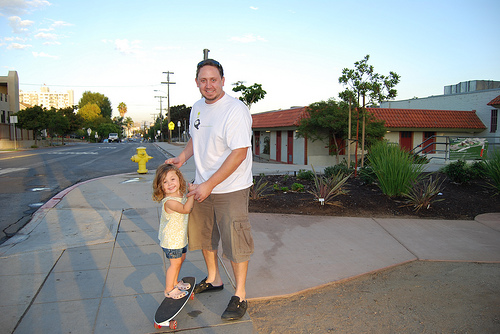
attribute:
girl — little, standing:
[159, 161, 195, 296]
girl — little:
[153, 167, 203, 298]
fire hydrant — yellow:
[127, 144, 157, 175]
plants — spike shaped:
[363, 140, 421, 201]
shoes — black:
[188, 276, 248, 326]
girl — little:
[143, 163, 203, 302]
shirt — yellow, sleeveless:
[153, 192, 193, 247]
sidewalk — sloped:
[1, 148, 185, 332]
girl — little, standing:
[145, 164, 207, 300]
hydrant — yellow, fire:
[127, 142, 154, 182]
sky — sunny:
[4, 4, 498, 118]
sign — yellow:
[160, 116, 180, 134]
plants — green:
[358, 135, 436, 211]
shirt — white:
[181, 94, 263, 199]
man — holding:
[163, 56, 260, 320]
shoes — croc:
[163, 277, 199, 301]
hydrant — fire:
[125, 140, 157, 178]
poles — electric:
[146, 67, 177, 142]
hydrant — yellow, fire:
[128, 141, 162, 185]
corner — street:
[82, 159, 193, 208]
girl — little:
[149, 160, 206, 306]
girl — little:
[148, 155, 203, 301]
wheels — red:
[148, 291, 204, 331]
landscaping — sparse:
[256, 145, 498, 219]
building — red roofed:
[245, 98, 495, 180]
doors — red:
[398, 129, 444, 158]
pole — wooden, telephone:
[157, 65, 188, 148]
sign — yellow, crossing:
[165, 118, 179, 133]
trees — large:
[20, 85, 131, 148]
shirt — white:
[187, 93, 252, 200]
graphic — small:
[184, 115, 210, 140]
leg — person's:
[165, 257, 181, 297]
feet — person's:
[163, 288, 192, 302]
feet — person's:
[159, 284, 195, 300]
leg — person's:
[205, 248, 221, 282]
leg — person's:
[232, 257, 246, 302]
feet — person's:
[194, 279, 224, 291]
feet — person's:
[219, 297, 248, 322]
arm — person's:
[190, 148, 246, 204]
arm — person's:
[190, 144, 248, 205]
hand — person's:
[188, 179, 213, 206]